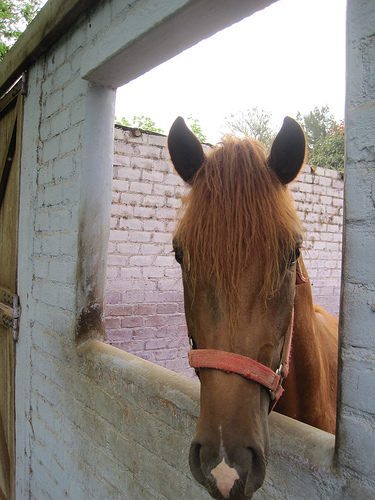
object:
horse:
[152, 104, 340, 500]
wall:
[102, 126, 344, 383]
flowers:
[335, 131, 338, 135]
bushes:
[294, 98, 345, 171]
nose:
[189, 429, 266, 498]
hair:
[171, 135, 303, 352]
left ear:
[262, 112, 305, 186]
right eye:
[173, 238, 189, 270]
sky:
[0, 0, 348, 167]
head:
[166, 115, 310, 500]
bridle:
[186, 289, 296, 416]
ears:
[163, 113, 206, 185]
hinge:
[10, 294, 23, 342]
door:
[1, 69, 29, 500]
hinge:
[21, 72, 29, 96]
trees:
[0, 0, 41, 60]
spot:
[208, 441, 242, 500]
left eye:
[284, 242, 305, 265]